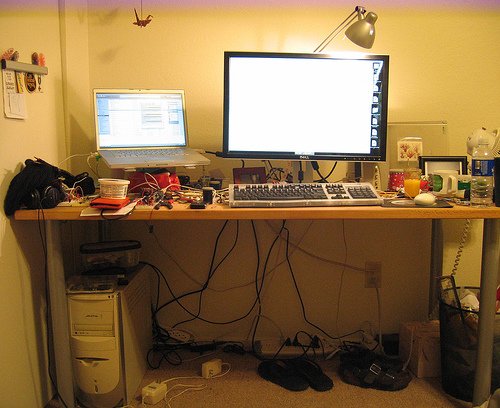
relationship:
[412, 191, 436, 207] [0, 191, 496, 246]
mouse sitting on desk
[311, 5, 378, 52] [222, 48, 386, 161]
desk lamp shining on monitor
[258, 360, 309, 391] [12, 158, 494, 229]
flip flop under table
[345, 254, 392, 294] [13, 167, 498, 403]
outlet under desk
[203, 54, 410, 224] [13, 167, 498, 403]
computer on desk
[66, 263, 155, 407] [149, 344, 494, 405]
computer on floor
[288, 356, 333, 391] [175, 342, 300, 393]
flip flop on floor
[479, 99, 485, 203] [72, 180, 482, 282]
bottle on desk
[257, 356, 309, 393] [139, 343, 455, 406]
flip flop on floor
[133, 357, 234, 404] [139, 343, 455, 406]
cables on floor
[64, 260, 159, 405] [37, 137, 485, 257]
computer under desk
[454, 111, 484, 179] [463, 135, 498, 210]
bottle of water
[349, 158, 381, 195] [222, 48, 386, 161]
speaker behind monitor